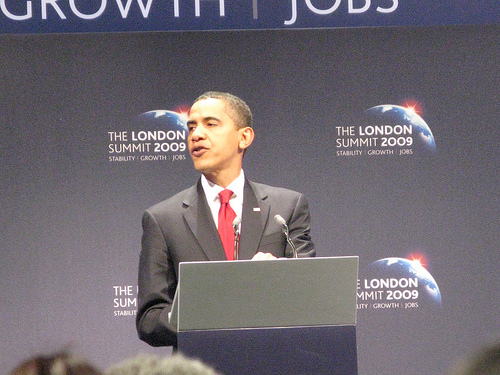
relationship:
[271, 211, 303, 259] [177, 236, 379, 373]
microphone on podium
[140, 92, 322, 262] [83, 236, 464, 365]
man giving speech at podium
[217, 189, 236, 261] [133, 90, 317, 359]
tie on man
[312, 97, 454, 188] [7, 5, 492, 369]
graphic on backdrop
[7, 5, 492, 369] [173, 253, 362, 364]
backdrop of podium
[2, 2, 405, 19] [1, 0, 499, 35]
lettering on banner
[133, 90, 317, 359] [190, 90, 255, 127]
man has hair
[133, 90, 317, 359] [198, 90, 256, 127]
man has hair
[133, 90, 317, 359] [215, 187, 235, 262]
man wearing tie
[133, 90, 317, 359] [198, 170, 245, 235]
man wearing shirt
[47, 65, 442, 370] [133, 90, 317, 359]
wall behind man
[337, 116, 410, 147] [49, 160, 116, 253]
white writing on blue wall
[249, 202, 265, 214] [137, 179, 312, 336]
lapel pin on jacket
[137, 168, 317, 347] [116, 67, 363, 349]
suit on man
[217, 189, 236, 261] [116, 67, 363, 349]
tie on man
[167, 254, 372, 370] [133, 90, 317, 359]
podium in front man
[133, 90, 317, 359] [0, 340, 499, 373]
man talking to audience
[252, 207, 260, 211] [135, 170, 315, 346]
lapel pin on jacket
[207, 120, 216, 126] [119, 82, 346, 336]
eye of man